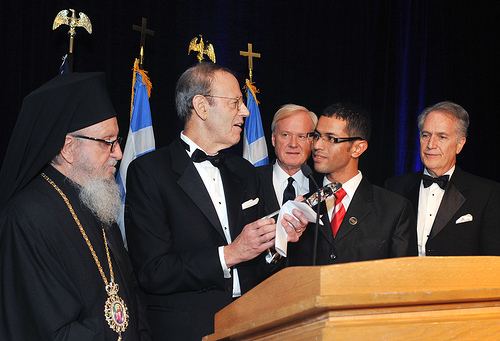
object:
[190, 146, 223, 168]
bowtie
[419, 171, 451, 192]
bowtie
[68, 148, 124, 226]
beard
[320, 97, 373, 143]
hair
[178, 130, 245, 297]
shirt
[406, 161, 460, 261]
shirt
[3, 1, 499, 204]
curtain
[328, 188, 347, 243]
tie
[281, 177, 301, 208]
tie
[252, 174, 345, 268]
award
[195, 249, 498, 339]
podium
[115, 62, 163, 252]
flag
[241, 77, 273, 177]
flag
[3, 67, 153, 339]
priest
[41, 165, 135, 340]
necklace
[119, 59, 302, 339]
man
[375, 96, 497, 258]
man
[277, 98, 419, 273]
man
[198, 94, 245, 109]
glasses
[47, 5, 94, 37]
eagle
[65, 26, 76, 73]
pole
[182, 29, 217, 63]
eagle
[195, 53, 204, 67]
pole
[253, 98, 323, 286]
man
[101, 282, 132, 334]
medallion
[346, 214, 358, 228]
pin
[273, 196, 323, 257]
item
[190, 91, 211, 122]
ear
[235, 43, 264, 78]
cross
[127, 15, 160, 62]
cross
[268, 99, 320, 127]
hair